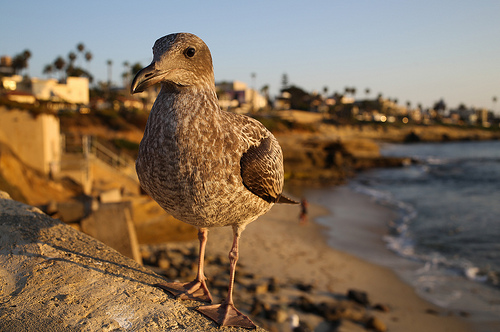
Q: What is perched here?
A: Bird.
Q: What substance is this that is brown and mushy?
A: Mud.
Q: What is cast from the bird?
A: Shadow.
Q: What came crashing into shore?
A: Waves.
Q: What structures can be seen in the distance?
A: Houses.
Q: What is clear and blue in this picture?
A: Sky.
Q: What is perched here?
A: Bird.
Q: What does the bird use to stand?
A: Is legs.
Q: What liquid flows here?
A: Water.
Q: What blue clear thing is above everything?
A: Sky.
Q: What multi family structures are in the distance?
A: Houses.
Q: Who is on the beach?
A: A bird.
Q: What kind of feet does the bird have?
A: Webbed feet.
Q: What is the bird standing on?
A: A rock.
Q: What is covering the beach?
A: Sand and rocks.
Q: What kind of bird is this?
A: A seagull.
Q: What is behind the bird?
A: A beach.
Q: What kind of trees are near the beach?
A: Palm trees.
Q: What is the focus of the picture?
A: The bird.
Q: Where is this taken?
A: On a beach.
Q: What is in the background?
A: Houses and a beach.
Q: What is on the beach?
A: Rocks and a person.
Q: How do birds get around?
A: Flying.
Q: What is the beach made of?
A: Water and sand.